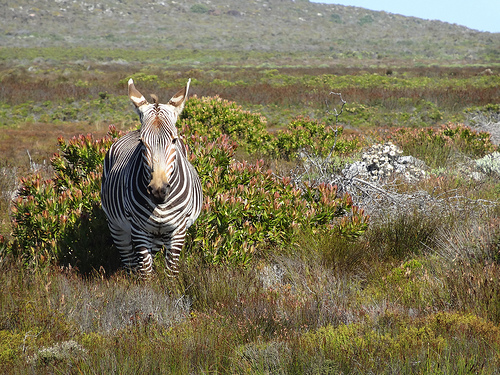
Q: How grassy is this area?
A: Very grassy.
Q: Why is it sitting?
A: Relaxing.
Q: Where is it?
A: Grassland.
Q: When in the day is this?
A: Afternoon.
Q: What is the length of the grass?
A: High.